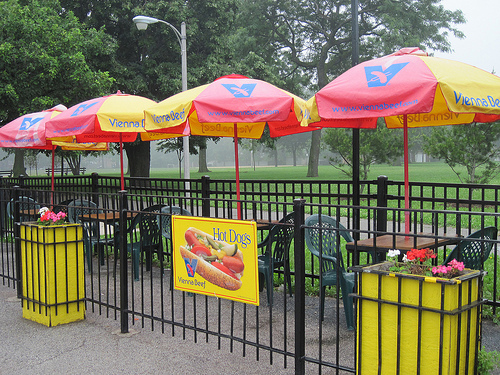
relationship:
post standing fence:
[129, 12, 199, 210] [14, 168, 484, 305]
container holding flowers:
[345, 269, 482, 362] [384, 241, 470, 280]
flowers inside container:
[381, 241, 479, 281] [349, 264, 484, 371]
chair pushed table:
[441, 223, 484, 274] [342, 227, 458, 297]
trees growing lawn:
[2, 3, 468, 180] [2, 161, 482, 216]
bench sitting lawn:
[34, 156, 85, 175] [2, 161, 482, 216]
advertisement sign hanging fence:
[169, 214, 264, 307] [5, 173, 484, 371]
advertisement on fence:
[164, 207, 264, 312] [5, 173, 484, 371]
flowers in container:
[381, 241, 479, 281] [345, 269, 482, 362]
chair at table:
[306, 215, 364, 333] [344, 226, 451, 304]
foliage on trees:
[4, 1, 473, 104] [3, 3, 484, 194]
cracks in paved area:
[0, 330, 95, 371] [0, 243, 403, 373]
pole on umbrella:
[394, 109, 416, 236] [301, 30, 484, 253]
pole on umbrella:
[229, 119, 249, 222] [139, 63, 318, 233]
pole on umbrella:
[106, 123, 130, 193] [42, 84, 177, 189]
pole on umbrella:
[40, 145, 60, 196] [2, 100, 116, 219]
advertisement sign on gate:
[169, 214, 264, 307] [9, 192, 374, 366]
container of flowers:
[14, 213, 84, 323] [32, 203, 71, 221]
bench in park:
[37, 163, 86, 179] [3, 6, 471, 214]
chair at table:
[306, 215, 364, 333] [341, 223, 456, 258]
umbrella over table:
[311, 48, 500, 240] [11, 193, 474, 347]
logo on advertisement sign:
[177, 254, 197, 282] [169, 214, 264, 307]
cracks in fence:
[6, 311, 110, 365] [14, 186, 410, 359]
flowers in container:
[381, 241, 479, 281] [344, 242, 493, 371]